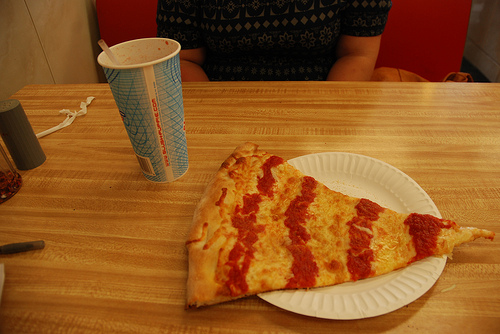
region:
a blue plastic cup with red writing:
[93, 35, 190, 182]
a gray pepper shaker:
[1, 103, 46, 172]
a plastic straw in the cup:
[97, 40, 118, 64]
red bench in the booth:
[99, 1, 469, 82]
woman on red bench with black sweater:
[157, 0, 390, 84]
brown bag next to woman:
[377, 65, 473, 82]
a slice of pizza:
[186, 145, 492, 306]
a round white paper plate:
[252, 150, 447, 320]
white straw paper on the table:
[36, 98, 96, 138]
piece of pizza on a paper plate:
[186, 142, 495, 320]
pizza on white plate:
[180, 128, 425, 305]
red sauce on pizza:
[192, 144, 393, 298]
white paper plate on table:
[222, 160, 469, 318]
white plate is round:
[202, 120, 464, 314]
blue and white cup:
[112, 30, 199, 194]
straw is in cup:
[92, 27, 163, 101]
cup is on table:
[104, 31, 212, 173]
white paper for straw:
[48, 100, 110, 155]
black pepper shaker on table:
[4, 90, 49, 155]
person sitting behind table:
[177, 3, 345, 87]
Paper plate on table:
[254, 145, 455, 322]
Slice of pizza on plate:
[185, 130, 497, 310]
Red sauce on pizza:
[340, 195, 388, 289]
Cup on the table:
[83, 30, 195, 189]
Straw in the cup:
[89, 34, 123, 67]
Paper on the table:
[35, 93, 97, 139]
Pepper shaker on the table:
[0, 83, 61, 173]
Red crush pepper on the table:
[0, 145, 25, 203]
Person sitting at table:
[147, 2, 397, 92]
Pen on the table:
[0, 228, 52, 283]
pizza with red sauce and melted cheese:
[178, 144, 492, 301]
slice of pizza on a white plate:
[185, 140, 455, 312]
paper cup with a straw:
[91, 30, 191, 184]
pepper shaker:
[0, 100, 44, 170]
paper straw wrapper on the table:
[36, 90, 90, 140]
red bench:
[396, 0, 458, 67]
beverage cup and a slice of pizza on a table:
[96, 38, 498, 318]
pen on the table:
[1, 235, 45, 252]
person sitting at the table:
[170, 0, 377, 90]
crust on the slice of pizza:
[183, 135, 253, 319]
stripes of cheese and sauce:
[231, 138, 491, 332]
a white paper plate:
[263, 144, 439, 320]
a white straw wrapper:
[34, 94, 101, 136]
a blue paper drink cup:
[96, 30, 188, 186]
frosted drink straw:
[92, 37, 122, 65]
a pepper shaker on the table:
[0, 98, 47, 170]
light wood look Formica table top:
[3, 84, 498, 331]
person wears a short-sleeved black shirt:
[157, 7, 383, 77]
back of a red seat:
[93, 2, 466, 84]